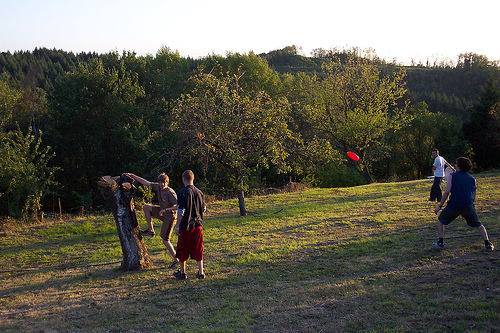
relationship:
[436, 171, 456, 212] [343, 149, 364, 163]
arm extension threw frisbee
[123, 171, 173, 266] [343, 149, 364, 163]
wrong position catch frisbee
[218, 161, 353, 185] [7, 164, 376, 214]
hedges on border field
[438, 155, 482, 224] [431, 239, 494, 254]
boys on sneaker feet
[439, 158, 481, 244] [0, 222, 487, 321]
boys in field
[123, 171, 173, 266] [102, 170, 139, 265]
boy on stamp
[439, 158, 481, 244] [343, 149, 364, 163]
boys playing frisbee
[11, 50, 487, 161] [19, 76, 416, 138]
hill full of trees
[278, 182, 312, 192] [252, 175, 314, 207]
pile of dirt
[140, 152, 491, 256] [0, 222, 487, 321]
men on field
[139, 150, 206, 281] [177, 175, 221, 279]
guys looking at each other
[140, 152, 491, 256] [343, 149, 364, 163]
men playing frisbee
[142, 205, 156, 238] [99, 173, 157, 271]
foot on treebark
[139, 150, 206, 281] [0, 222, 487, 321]
guys standing on field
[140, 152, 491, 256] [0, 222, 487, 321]
fourmen on field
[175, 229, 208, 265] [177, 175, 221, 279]
shorts worn by boy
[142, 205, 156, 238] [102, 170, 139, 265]
foot on tree stump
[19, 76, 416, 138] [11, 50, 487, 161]
trees in background